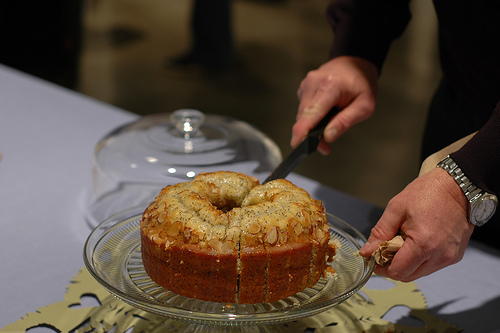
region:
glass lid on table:
[70, 90, 320, 208]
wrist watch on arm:
[416, 141, 493, 230]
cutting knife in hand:
[259, 85, 346, 210]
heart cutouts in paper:
[62, 287, 136, 324]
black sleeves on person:
[440, 118, 496, 176]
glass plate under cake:
[67, 162, 352, 329]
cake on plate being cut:
[117, 150, 358, 304]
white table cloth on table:
[10, 74, 456, 327]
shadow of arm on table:
[411, 294, 462, 327]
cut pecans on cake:
[242, 228, 312, 258]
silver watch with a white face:
[434, 147, 499, 233]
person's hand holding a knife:
[250, 48, 385, 187]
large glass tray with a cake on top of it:
[77, 161, 376, 332]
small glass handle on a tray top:
[168, 104, 210, 138]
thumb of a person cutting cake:
[318, 88, 380, 146]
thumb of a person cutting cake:
[356, 202, 406, 259]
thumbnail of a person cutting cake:
[324, 125, 339, 142]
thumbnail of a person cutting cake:
[359, 239, 372, 256]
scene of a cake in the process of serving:
[10, 5, 487, 318]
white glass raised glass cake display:
[82, 200, 375, 329]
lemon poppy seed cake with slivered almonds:
[139, 170, 337, 300]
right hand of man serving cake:
[286, 56, 382, 151]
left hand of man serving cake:
[358, 165, 475, 282]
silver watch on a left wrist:
[437, 153, 497, 229]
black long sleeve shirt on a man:
[334, 2, 497, 203]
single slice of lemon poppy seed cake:
[238, 200, 269, 304]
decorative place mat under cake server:
[0, 215, 462, 332]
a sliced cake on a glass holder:
[127, 166, 328, 305]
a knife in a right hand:
[265, 53, 371, 203]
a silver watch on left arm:
[430, 151, 499, 231]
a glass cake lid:
[82, 111, 281, 214]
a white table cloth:
[0, 65, 80, 232]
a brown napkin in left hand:
[362, 196, 432, 273]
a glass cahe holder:
[87, 207, 374, 329]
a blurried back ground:
[10, 0, 301, 77]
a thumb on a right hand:
[323, 98, 371, 145]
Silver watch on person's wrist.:
[435, 158, 494, 225]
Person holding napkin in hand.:
[370, 229, 415, 275]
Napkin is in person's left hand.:
[374, 215, 411, 285]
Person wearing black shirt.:
[468, 140, 486, 162]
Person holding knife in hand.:
[264, 109, 317, 168]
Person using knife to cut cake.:
[259, 132, 306, 209]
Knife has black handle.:
[307, 113, 342, 161]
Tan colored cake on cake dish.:
[148, 174, 360, 321]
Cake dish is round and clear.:
[87, 212, 314, 327]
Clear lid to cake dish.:
[93, 101, 216, 186]